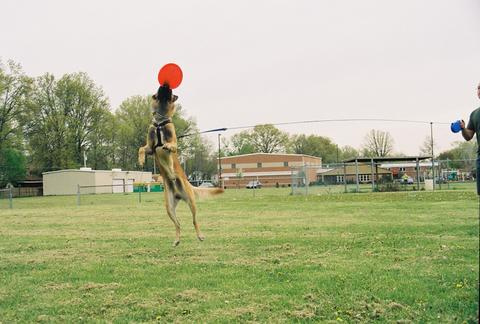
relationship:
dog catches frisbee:
[133, 82, 204, 248] [156, 62, 188, 91]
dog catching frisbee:
[133, 82, 204, 248] [156, 62, 188, 91]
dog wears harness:
[133, 82, 204, 248] [144, 123, 172, 156]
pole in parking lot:
[212, 130, 225, 189] [195, 175, 320, 189]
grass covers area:
[63, 227, 124, 261] [11, 184, 479, 320]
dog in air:
[133, 82, 204, 248] [16, 75, 459, 192]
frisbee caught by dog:
[156, 62, 188, 91] [133, 82, 204, 248]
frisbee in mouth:
[156, 62, 188, 91] [157, 83, 177, 88]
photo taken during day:
[1, 1, 480, 321] [9, 3, 422, 123]